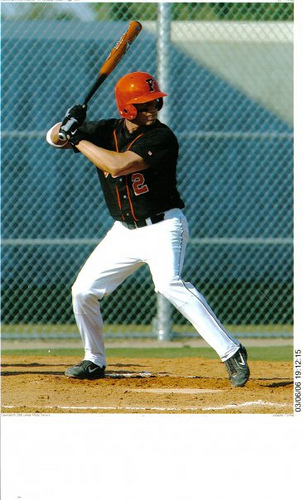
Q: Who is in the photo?
A: The batter.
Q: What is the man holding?
A: A bat.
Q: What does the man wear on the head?
A: A helmet.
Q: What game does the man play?
A: Baseball.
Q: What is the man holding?
A: A baseball bat.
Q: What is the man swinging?
A: Baseball bat.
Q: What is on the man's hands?
A: Gloves.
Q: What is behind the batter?
A: A silver chain link fence.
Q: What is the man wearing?
A: White pants.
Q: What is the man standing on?
A: A home plate.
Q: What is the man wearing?
A: Baseball uniform.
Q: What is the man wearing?
A: A baseball uniform.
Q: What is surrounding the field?
A: A chain link fence.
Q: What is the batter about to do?
A: Swing.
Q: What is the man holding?
A: A bat.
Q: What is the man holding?
A: A brown bat with black handle.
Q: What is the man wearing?
A: A black shirt with an orange stripe.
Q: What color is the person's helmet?
A: Orange.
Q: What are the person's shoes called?
A: Cleats.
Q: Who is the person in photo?
A: Man.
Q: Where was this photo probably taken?
A: Baseball field.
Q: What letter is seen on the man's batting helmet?
A: P.